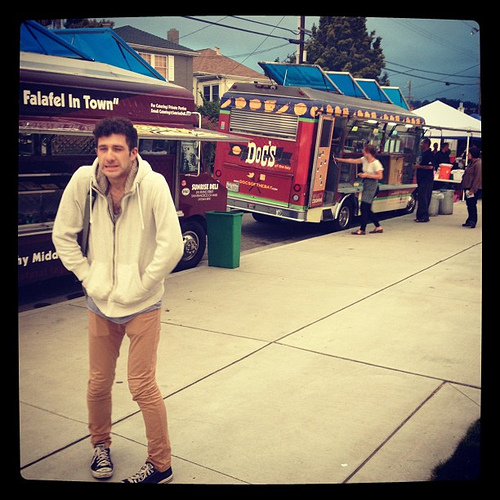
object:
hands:
[83, 277, 146, 302]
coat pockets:
[80, 262, 115, 301]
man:
[50, 120, 185, 483]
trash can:
[207, 207, 242, 270]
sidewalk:
[19, 191, 490, 480]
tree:
[304, 12, 388, 85]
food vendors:
[13, 50, 255, 287]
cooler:
[434, 163, 453, 181]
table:
[425, 177, 466, 193]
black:
[411, 136, 438, 222]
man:
[410, 138, 438, 222]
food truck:
[213, 83, 428, 230]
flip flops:
[349, 229, 371, 237]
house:
[108, 25, 201, 100]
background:
[20, 13, 483, 486]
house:
[192, 42, 283, 110]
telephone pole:
[299, 13, 308, 64]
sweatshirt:
[51, 151, 186, 318]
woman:
[458, 151, 483, 228]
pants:
[463, 186, 481, 228]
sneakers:
[121, 461, 174, 484]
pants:
[86, 307, 171, 472]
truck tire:
[171, 215, 207, 269]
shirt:
[415, 148, 438, 186]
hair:
[90, 118, 142, 158]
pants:
[415, 176, 433, 223]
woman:
[336, 143, 385, 235]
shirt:
[359, 156, 384, 177]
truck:
[19, 51, 231, 293]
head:
[94, 115, 139, 179]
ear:
[130, 146, 140, 161]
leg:
[125, 308, 172, 472]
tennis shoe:
[85, 441, 114, 478]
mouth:
[102, 162, 121, 174]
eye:
[112, 145, 126, 153]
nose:
[105, 151, 114, 161]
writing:
[22, 89, 115, 112]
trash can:
[424, 188, 440, 215]